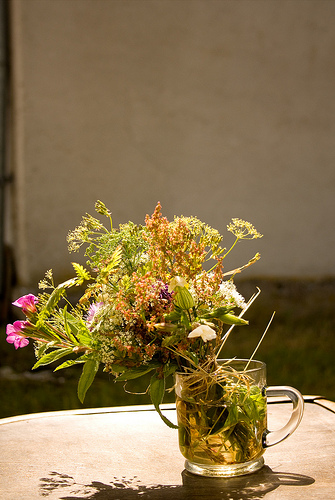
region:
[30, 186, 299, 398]
Flowers in a glass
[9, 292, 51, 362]
purple flowers in a glass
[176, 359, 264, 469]
roots in a glass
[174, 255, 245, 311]
white flowers in the glass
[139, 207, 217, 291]
brown flowers in the glass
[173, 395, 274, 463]
water in the glass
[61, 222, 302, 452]
multi color flowers in the glass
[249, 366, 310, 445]
handle on the glass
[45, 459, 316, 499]
shadow on the table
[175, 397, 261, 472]
brown water in the glass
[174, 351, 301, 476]
a clear glass cup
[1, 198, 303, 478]
flowers displayed in a glass cup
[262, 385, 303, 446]
the handle of a cup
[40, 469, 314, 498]
the shadow of flowers and a cup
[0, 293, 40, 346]
two pink flowers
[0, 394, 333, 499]
a table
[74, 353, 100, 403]
a green leaf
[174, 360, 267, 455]
the stems of a bunch of flowers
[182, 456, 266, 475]
the base of a clear glass cup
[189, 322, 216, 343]
a small white flower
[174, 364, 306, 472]
A clear flower vase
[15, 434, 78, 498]
A brown dirty surface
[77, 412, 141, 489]
A brown dirty surface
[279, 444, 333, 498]
A brown dirty surface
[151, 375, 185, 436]
A green flower leaf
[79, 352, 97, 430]
A green flower leaf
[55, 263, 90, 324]
A green flower leaf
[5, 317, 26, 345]
A small purple flower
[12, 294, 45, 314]
A small purple flower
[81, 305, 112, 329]
A small purple flower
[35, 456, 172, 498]
shadow of flowers on the table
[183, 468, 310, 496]
shadow of glass mug on the table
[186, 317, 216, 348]
white flower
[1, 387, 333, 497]
table mug of flowers is sitting on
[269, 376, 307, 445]
handle of glass mug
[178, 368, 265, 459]
stems of plants in glass mug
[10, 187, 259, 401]
bouquet of flowers stuck in mug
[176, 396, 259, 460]
water in the glass mug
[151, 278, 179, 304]
purple flower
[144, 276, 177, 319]
A small purple flower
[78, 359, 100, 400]
A small green leaf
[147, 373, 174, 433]
A small green leaf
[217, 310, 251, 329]
A small green leaf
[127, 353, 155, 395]
A small green leaf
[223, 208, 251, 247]
A white flowering plant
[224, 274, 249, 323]
A white flowering plant